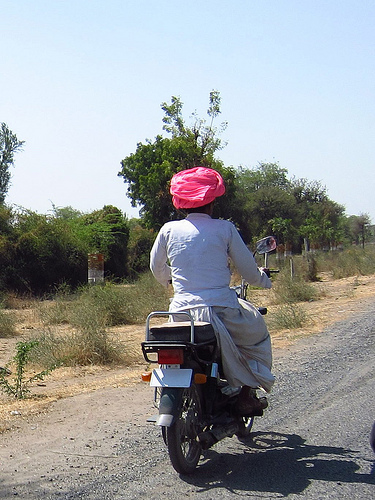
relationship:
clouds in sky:
[0, 0, 373, 225] [0, 1, 373, 226]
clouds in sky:
[0, 0, 373, 225] [0, 0, 373, 146]